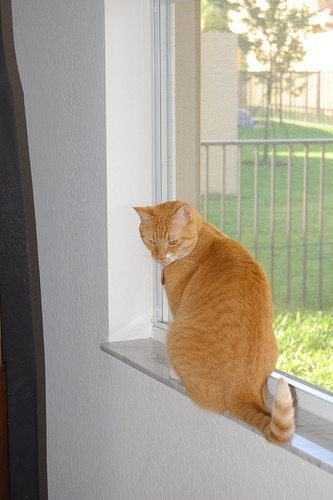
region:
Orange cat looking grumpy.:
[127, 187, 223, 268]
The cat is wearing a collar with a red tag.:
[151, 262, 174, 288]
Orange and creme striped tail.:
[254, 368, 300, 453]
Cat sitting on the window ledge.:
[103, 160, 266, 371]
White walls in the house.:
[60, 392, 147, 489]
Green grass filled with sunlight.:
[280, 306, 327, 372]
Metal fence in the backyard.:
[205, 132, 327, 225]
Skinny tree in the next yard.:
[226, 1, 316, 138]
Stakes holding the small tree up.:
[239, 91, 295, 153]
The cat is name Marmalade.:
[122, 174, 214, 290]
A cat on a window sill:
[130, 192, 330, 468]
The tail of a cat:
[245, 373, 299, 451]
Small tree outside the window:
[230, 2, 311, 167]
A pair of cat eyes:
[141, 229, 184, 250]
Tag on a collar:
[150, 261, 182, 287]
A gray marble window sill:
[95, 335, 330, 474]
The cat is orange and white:
[128, 196, 304, 451]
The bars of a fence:
[201, 134, 331, 310]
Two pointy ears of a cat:
[130, 199, 196, 226]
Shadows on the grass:
[198, 118, 331, 316]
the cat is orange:
[146, 199, 282, 465]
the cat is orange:
[134, 173, 241, 405]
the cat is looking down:
[125, 202, 190, 287]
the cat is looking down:
[117, 177, 226, 333]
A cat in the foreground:
[128, 182, 312, 451]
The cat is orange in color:
[123, 191, 310, 444]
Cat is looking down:
[126, 195, 200, 268]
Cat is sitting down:
[133, 187, 310, 447]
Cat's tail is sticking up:
[258, 370, 301, 448]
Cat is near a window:
[167, 3, 332, 391]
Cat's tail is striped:
[237, 367, 304, 448]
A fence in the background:
[241, 64, 331, 125]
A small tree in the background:
[232, 1, 314, 166]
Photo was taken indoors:
[1, 3, 332, 495]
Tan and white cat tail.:
[268, 382, 296, 445]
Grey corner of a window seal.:
[102, 341, 154, 373]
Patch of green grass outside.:
[285, 302, 329, 365]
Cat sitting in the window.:
[130, 195, 297, 450]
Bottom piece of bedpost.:
[4, 359, 54, 487]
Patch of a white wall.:
[90, 398, 190, 479]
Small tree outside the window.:
[235, 6, 293, 100]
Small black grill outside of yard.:
[237, 99, 258, 137]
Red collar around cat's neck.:
[160, 268, 169, 284]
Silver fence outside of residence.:
[203, 139, 331, 208]